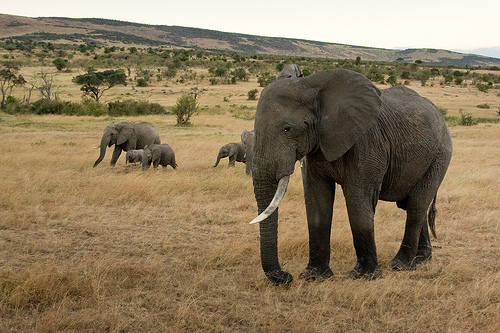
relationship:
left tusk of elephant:
[249, 181, 293, 224] [250, 67, 452, 291]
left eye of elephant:
[281, 123, 297, 136] [250, 67, 452, 291]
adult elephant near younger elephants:
[99, 122, 158, 147] [127, 148, 179, 168]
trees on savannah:
[0, 31, 499, 122] [0, 16, 498, 330]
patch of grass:
[0, 182, 244, 332] [1, 136, 498, 332]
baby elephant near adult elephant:
[126, 149, 144, 164] [99, 122, 158, 147]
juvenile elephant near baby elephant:
[144, 143, 180, 169] [126, 149, 144, 164]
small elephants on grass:
[209, 137, 251, 172] [1, 136, 498, 332]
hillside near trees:
[0, 14, 498, 66] [0, 31, 499, 122]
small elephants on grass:
[127, 132, 251, 167] [1, 136, 498, 332]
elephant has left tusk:
[250, 67, 452, 291] [249, 181, 293, 224]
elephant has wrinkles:
[250, 67, 452, 291] [379, 103, 442, 163]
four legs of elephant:
[301, 178, 430, 277] [250, 67, 452, 291]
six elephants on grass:
[94, 67, 455, 284] [1, 136, 498, 332]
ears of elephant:
[280, 62, 381, 163] [250, 67, 452, 291]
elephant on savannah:
[250, 67, 452, 291] [0, 16, 498, 330]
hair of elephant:
[425, 204, 442, 241] [250, 67, 452, 291]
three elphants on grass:
[93, 119, 178, 174] [1, 136, 498, 332]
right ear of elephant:
[274, 63, 300, 79] [250, 67, 452, 291]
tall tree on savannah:
[0, 66, 26, 112] [0, 16, 498, 330]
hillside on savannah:
[0, 14, 498, 66] [0, 16, 498, 330]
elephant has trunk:
[250, 67, 452, 291] [250, 170, 294, 286]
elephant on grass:
[250, 67, 452, 291] [1, 136, 498, 332]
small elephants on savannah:
[127, 132, 251, 167] [0, 16, 498, 330]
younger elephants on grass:
[127, 148, 179, 168] [1, 136, 498, 332]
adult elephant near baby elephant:
[99, 122, 158, 147] [126, 149, 144, 164]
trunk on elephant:
[250, 170, 294, 286] [250, 67, 452, 291]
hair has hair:
[425, 204, 442, 241] [429, 214, 439, 240]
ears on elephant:
[280, 62, 381, 163] [250, 67, 452, 291]